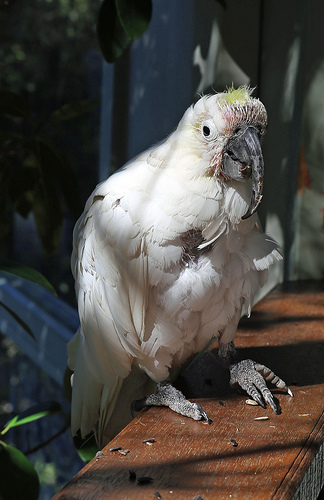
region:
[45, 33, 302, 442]
this is a parrot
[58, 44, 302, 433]
this parrot looks sick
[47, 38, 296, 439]
sick birds pluck feathers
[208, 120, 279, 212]
the beak is sharp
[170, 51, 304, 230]
the beak is black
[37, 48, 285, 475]
the parrot is white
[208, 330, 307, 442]
three claws on a foot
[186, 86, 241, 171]
the eye is black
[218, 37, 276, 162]
tuft of yellow feathers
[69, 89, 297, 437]
a white bird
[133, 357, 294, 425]
the feet of the bird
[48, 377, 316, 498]
a wood platform the bird is on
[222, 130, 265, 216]
the beak of the bird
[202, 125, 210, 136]
the eye of the bird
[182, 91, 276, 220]
the face of the bird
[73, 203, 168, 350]
the wing of the bird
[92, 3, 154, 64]
the large leaves behind the bird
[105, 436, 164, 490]
seeds on the ledge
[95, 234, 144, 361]
a white feather on the bird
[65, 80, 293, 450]
the large white bird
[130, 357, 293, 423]
the bird's two feet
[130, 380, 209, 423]
the bird's foot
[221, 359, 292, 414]
the bird's foot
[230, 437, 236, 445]
the seed near the bird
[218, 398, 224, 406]
the seed near the bird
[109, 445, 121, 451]
the seed near the bird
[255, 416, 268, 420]
the seed near the bird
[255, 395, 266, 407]
the nail on the bird's foot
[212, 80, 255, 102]
the yellow feathers on the top of the bird's head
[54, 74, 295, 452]
the white parrot is old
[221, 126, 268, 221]
beak of parrot is curved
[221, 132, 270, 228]
beak of parrot is color black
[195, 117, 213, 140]
eye of parrot is black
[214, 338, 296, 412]
right leg of parrot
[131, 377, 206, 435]
left leg of parrot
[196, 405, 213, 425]
claws of parrot are black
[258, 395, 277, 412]
claws of parrot are black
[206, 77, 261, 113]
green feathers on head of parrot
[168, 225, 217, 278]
bald part on breast of parrot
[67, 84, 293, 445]
A parrot is standing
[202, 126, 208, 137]
Eye ball is black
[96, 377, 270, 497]
Seeds on the ground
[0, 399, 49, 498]
A couple of green leaves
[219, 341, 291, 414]
Claws are gray and black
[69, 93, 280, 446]
The feathers are white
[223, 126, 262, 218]
The beak is black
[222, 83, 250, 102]
A yellow tuft of hair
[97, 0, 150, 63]
Two leaves hanging down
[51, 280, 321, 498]
Panel is made of wood